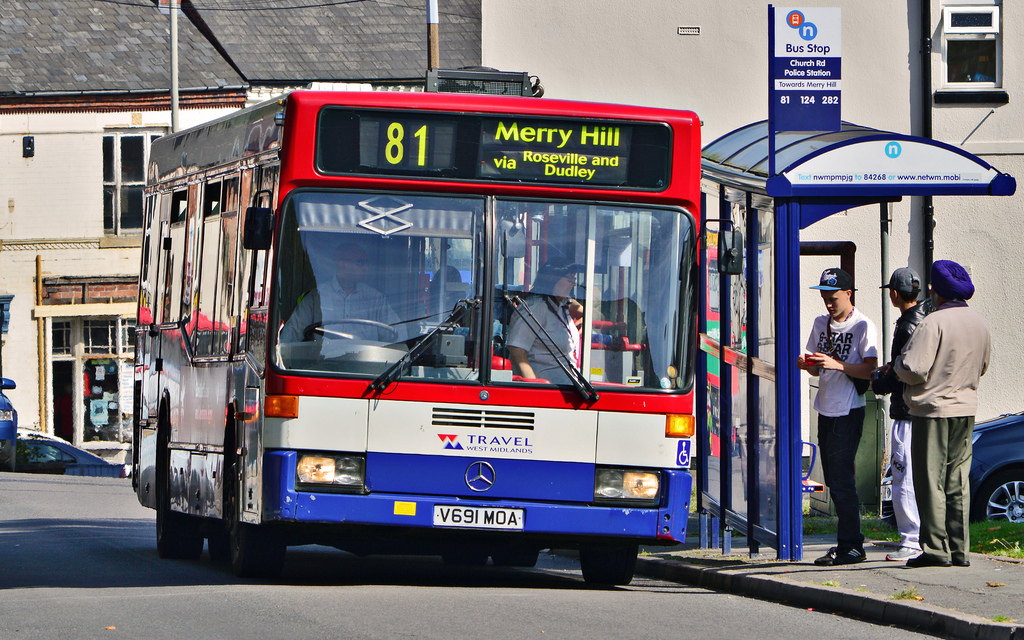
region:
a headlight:
[611, 462, 668, 504]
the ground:
[453, 599, 559, 634]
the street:
[389, 583, 470, 637]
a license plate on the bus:
[430, 501, 520, 530]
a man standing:
[800, 279, 880, 546]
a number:
[377, 117, 442, 172]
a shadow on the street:
[28, 509, 142, 587]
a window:
[298, 213, 453, 360]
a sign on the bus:
[456, 460, 505, 496]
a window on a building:
[104, 130, 118, 188]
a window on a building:
[117, 126, 150, 183]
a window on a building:
[103, 180, 122, 228]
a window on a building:
[117, 186, 138, 231]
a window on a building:
[54, 329, 78, 355]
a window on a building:
[69, 320, 120, 346]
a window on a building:
[75, 352, 111, 438]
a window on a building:
[941, 38, 987, 84]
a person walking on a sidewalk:
[786, 262, 900, 558]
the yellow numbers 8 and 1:
[381, 110, 442, 178]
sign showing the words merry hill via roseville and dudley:
[473, 113, 677, 194]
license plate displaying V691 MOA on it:
[420, 499, 539, 526]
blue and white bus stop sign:
[764, 3, 848, 139]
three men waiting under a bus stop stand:
[698, 91, 1016, 595]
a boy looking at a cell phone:
[797, 271, 873, 562]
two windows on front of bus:
[272, 168, 703, 418]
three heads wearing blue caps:
[808, 241, 980, 312]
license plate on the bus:
[439, 503, 529, 533]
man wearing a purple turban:
[928, 259, 982, 301]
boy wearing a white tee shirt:
[802, 312, 879, 414]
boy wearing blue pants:
[805, 389, 876, 535]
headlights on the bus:
[293, 449, 666, 525]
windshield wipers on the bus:
[389, 279, 604, 428]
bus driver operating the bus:
[305, 239, 403, 366]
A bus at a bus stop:
[146, 91, 707, 556]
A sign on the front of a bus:
[311, 110, 673, 187]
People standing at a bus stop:
[811, 259, 996, 566]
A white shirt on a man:
[795, 306, 868, 421]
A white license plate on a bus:
[425, 492, 536, 538]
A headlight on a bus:
[292, 448, 346, 494]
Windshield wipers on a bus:
[365, 282, 607, 410]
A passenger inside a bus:
[503, 257, 602, 378]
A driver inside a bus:
[272, 240, 413, 355]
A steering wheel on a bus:
[304, 312, 400, 351]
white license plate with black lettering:
[416, 497, 546, 532]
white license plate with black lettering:
[417, 487, 535, 548]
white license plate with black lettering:
[423, 486, 551, 543]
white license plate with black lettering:
[425, 487, 542, 530]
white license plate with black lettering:
[422, 487, 540, 544]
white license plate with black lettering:
[413, 487, 532, 548]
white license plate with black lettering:
[416, 492, 544, 534]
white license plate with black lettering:
[417, 484, 551, 536]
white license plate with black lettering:
[393, 481, 548, 539]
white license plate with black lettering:
[406, 490, 533, 544]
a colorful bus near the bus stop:
[130, 85, 703, 592]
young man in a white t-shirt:
[802, 266, 879, 564]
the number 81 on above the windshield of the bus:
[381, 116, 435, 171]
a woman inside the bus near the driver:
[506, 252, 586, 380]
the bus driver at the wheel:
[281, 241, 414, 347]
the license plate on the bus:
[429, 500, 528, 532]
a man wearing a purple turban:
[891, 253, 994, 566]